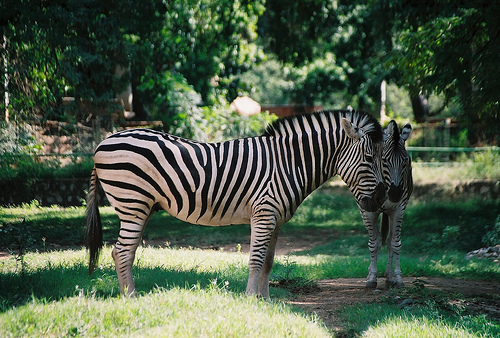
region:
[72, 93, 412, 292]
two zebras standing together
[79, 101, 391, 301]
zebra in the foreground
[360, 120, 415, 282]
zebra in the backgroundn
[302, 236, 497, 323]
patch of dirt in grassy area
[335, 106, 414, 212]
faces of two zebras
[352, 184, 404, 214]
black noses of two zebras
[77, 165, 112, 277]
tail of zebra in foreground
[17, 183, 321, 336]
sunlight spilling through the trees onto grass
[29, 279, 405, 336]
sunny spot on grass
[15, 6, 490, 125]
branches hanging over grassy area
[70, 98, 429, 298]
two zebras looking down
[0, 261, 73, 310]
shade behind the zebra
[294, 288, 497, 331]
shade in front of the zebras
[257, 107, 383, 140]
mane of the front zebra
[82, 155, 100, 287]
tail of the zebra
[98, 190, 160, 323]
right rear leg of the zebra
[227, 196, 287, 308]
right front leg of the zebra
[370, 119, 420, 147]
ears of a zebra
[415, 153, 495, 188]
sunny area in the distance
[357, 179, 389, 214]
dark nose of the zebra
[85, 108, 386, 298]
Black and white zebra standing in grass.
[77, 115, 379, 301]
a large zebra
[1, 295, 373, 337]
a zebra is standing on grass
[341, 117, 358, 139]
one of zebra ears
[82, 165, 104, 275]
a zebra tail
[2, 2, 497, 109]
trees are in the background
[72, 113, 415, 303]
two zebras stand near each other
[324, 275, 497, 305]
zebra standing in brown dirt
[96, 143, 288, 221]
zebra has black strips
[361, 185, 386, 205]
zebra's nose is black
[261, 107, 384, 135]
zebra has hair on top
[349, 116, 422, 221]
two zebras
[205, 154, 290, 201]
zebras are black and white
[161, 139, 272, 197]
zebras have stripes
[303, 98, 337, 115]
zebras have manes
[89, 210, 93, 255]
zebra's tail is bushy at the end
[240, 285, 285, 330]
zebra is standing in the grass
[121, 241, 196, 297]
shadow on the grass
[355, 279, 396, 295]
zebra is standing on the dirt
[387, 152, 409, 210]
zebra is standing in the shade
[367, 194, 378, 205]
zebra has a black nose